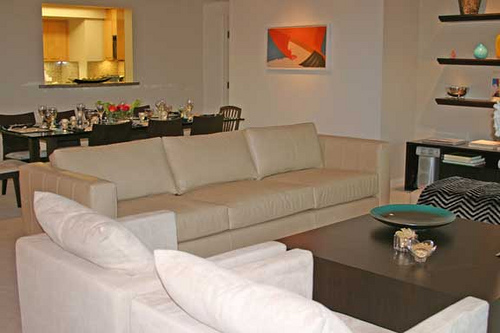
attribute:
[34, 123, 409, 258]
sofa — long, tan